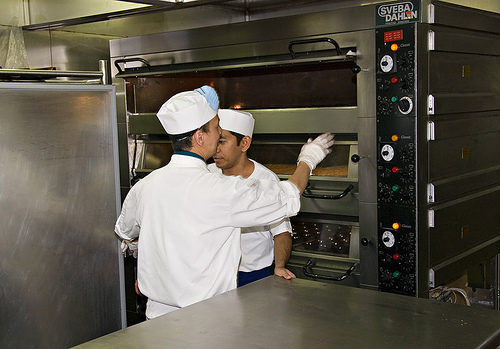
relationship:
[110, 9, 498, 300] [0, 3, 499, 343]
appliance in restaurant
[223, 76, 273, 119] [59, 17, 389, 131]
light in front appliance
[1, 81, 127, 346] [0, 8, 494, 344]
door on appliance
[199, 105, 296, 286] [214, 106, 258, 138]
person wearing hat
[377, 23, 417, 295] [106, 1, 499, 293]
knobs on oven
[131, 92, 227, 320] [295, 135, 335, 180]
cook has hands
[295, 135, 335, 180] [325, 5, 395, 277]
hands in oven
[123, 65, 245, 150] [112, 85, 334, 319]
hat on cook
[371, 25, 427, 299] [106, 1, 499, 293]
controls on oven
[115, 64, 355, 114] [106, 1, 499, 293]
window on oven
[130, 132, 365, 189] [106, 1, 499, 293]
window on oven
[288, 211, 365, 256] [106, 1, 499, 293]
window on oven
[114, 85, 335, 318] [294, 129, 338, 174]
baker has hand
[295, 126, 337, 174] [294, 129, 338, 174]
glove on hand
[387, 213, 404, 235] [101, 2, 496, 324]
amber light on appliance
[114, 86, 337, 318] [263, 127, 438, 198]
baker checking oven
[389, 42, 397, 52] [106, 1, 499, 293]
light on oven